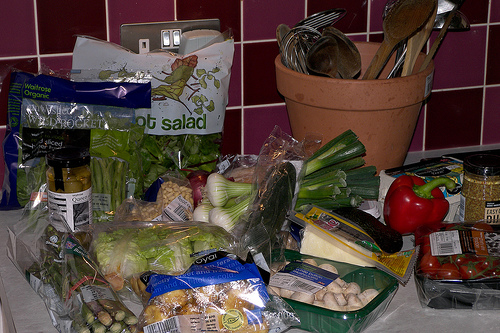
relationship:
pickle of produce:
[240, 159, 297, 254] [2, 34, 498, 331]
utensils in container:
[257, 5, 467, 79] [274, 40, 435, 177]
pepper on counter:
[383, 171, 455, 236] [2, 167, 497, 331]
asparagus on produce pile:
[26, 226, 139, 331] [0, 33, 498, 330]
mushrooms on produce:
[266, 258, 381, 312] [2, 34, 498, 331]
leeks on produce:
[191, 128, 381, 231] [2, 34, 498, 331]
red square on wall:
[425, 89, 486, 147] [426, 34, 498, 150]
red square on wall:
[431, 30, 483, 85] [426, 34, 498, 150]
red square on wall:
[240, 106, 287, 151] [426, 34, 498, 150]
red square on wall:
[243, 3, 297, 42] [426, 34, 498, 150]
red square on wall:
[2, 2, 37, 55] [426, 34, 498, 150]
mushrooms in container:
[185, 183, 376, 325] [117, 80, 474, 289]